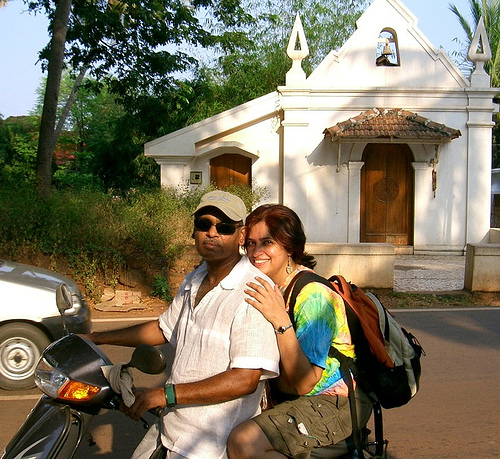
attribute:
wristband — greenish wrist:
[161, 380, 178, 410]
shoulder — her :
[258, 251, 339, 297]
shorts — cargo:
[251, 382, 374, 454]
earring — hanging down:
[286, 254, 298, 274]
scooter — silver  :
[26, 290, 178, 441]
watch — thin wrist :
[272, 320, 297, 335]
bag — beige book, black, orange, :
[285, 266, 428, 418]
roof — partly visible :
[49, 130, 95, 187]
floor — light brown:
[260, 143, 302, 227]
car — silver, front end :
[31, 275, 111, 325]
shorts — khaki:
[260, 401, 341, 446]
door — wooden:
[355, 138, 416, 248]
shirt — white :
[143, 248, 282, 388]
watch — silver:
[270, 320, 298, 334]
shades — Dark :
[194, 212, 244, 235]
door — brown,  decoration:
[365, 152, 413, 241]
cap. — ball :
[189, 186, 253, 225]